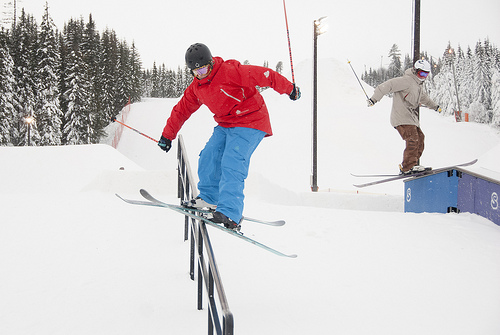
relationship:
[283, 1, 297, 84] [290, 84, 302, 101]
pole in hand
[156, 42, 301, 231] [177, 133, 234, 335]
person on railing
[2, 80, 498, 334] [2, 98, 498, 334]
snow on ground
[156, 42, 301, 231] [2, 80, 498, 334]
person on snow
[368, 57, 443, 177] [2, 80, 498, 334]
person on snow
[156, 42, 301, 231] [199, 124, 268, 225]
person wearing pants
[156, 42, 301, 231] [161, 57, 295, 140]
person wearing jacket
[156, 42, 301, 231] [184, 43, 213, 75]
person wearing helmet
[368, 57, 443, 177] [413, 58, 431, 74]
person wearing helmet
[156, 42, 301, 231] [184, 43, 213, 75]
person has helmet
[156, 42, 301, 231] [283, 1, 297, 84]
person holding pole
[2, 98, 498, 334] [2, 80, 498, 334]
ground has snow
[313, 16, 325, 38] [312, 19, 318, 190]
light on pole